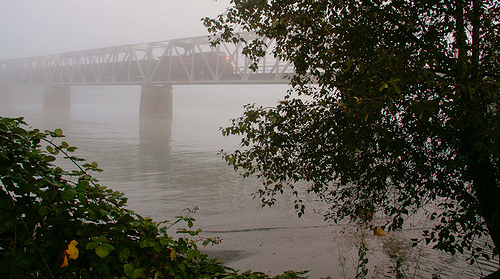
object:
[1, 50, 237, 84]
train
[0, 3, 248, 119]
fog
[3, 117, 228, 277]
bush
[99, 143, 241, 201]
waves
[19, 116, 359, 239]
water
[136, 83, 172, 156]
pylon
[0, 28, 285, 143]
bridge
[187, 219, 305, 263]
bank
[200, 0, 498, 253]
tree